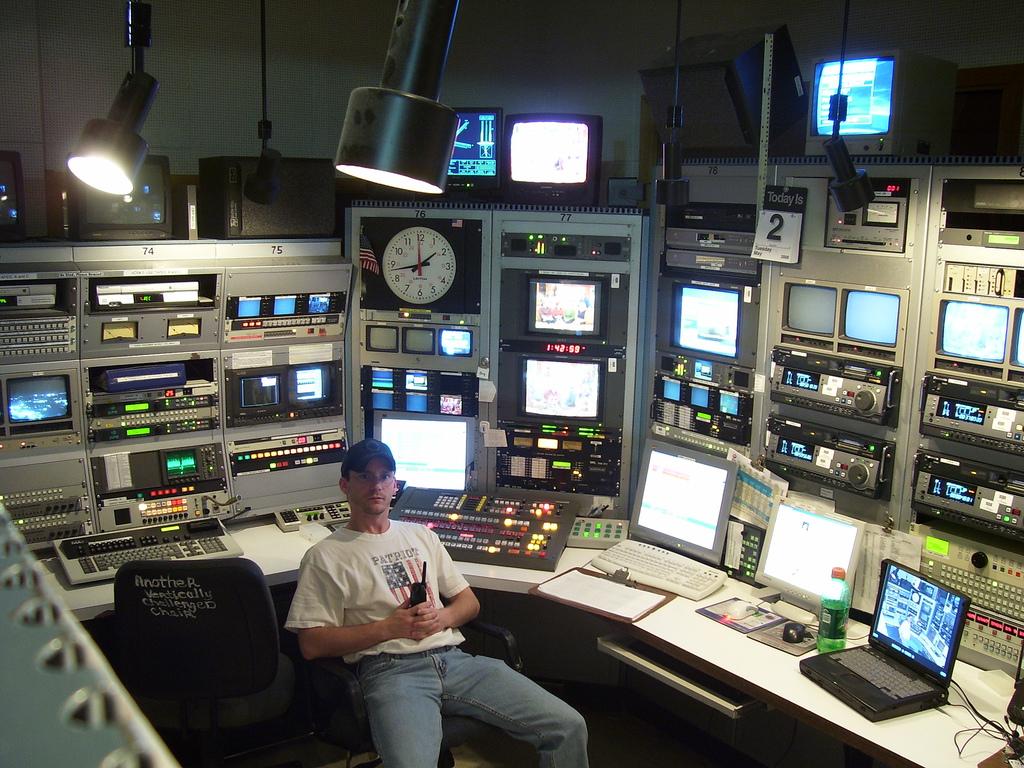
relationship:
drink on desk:
[799, 548, 870, 669] [660, 548, 870, 679]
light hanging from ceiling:
[52, 115, 157, 217] [76, 17, 282, 150]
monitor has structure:
[679, 284, 734, 357] [20, 130, 1023, 660]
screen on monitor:
[621, 437, 738, 571] [621, 437, 738, 571]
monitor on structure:
[378, 419, 465, 500] [378, 210, 486, 501]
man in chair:
[283, 441, 587, 767] [104, 545, 367, 741]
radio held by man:
[397, 550, 436, 604] [334, 449, 424, 533]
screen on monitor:
[11, 360, 88, 427] [11, 360, 88, 427]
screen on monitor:
[862, 553, 973, 689] [859, 557, 974, 676]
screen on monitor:
[501, 99, 618, 202] [501, 99, 618, 202]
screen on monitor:
[220, 282, 351, 346] [220, 282, 351, 346]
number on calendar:
[751, 184, 812, 277] [751, 184, 812, 277]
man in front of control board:
[306, 441, 504, 730] [375, 472, 619, 570]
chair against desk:
[90, 542, 309, 720] [90, 458, 395, 627]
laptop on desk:
[809, 558, 964, 724] [603, 479, 964, 724]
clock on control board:
[373, 226, 472, 310] [329, 180, 506, 520]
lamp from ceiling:
[315, 22, 532, 213] [315, 22, 532, 213]